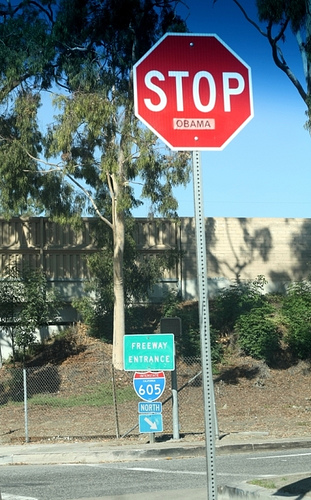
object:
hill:
[0, 281, 311, 431]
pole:
[191, 149, 219, 499]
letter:
[143, 68, 168, 114]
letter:
[167, 70, 188, 111]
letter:
[172, 117, 215, 129]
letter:
[192, 69, 217, 114]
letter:
[222, 71, 246, 114]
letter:
[132, 341, 168, 349]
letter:
[128, 355, 170, 363]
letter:
[138, 384, 161, 396]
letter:
[140, 404, 159, 413]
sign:
[123, 333, 175, 372]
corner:
[165, 447, 289, 499]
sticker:
[170, 115, 220, 132]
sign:
[132, 371, 167, 403]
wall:
[5, 216, 311, 273]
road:
[1, 439, 310, 499]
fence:
[0, 357, 203, 436]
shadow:
[270, 476, 311, 499]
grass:
[248, 464, 310, 496]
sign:
[132, 30, 253, 155]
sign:
[137, 402, 163, 433]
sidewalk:
[0, 455, 206, 495]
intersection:
[5, 330, 300, 499]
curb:
[19, 431, 306, 456]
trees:
[0, 6, 192, 361]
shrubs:
[221, 273, 311, 371]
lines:
[62, 451, 311, 480]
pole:
[150, 432, 155, 444]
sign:
[136, 402, 168, 414]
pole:
[170, 334, 179, 441]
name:
[137, 382, 165, 397]